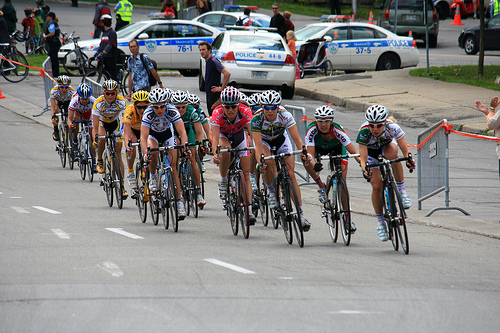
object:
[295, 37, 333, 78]
stroller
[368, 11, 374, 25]
traffic cones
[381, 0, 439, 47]
suv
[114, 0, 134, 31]
officer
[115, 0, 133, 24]
yellow vest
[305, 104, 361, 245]
racer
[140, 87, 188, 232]
racer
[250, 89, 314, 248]
racer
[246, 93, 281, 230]
racer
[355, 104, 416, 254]
bicyclists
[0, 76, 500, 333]
road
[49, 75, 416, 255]
alert bicyclists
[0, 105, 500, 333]
roadway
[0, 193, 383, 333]
lines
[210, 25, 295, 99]
cars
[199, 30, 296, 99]
car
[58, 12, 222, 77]
cruiser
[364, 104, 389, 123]
bicycle helmet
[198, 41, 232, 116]
man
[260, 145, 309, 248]
bicycle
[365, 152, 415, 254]
bicycle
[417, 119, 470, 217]
barricade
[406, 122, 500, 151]
tape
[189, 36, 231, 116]
man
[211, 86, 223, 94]
hands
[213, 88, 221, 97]
hips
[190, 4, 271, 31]
car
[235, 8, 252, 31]
people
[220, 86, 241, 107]
helmets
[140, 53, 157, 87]
backpack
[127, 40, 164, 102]
man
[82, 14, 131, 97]
man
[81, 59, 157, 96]
bicycle